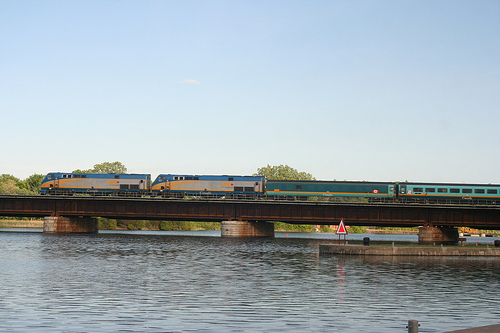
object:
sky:
[0, 0, 500, 181]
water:
[0, 227, 500, 333]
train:
[37, 170, 500, 205]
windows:
[486, 188, 498, 195]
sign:
[334, 218, 349, 236]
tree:
[12, 172, 47, 195]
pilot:
[47, 175, 51, 179]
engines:
[205, 186, 214, 191]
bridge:
[0, 193, 499, 245]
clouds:
[90, 68, 98, 73]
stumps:
[219, 219, 275, 239]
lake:
[0, 228, 500, 333]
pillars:
[42, 215, 99, 233]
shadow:
[274, 237, 349, 276]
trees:
[105, 167, 114, 171]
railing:
[0, 190, 500, 205]